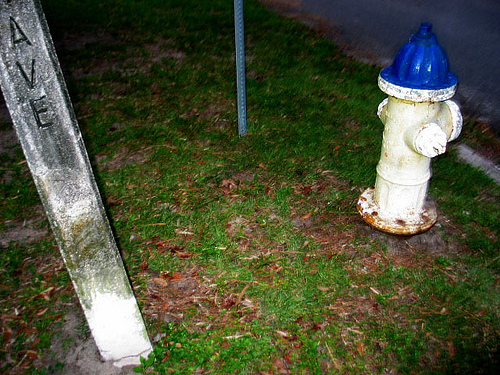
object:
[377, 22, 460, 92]
top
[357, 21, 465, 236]
fire hydrant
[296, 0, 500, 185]
road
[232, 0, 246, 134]
pole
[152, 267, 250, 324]
leaves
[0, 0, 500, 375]
ground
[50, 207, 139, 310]
moss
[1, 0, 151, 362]
post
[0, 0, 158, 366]
pillar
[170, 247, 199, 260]
leaf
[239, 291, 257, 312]
leaf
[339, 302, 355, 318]
leaf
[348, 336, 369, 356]
leaf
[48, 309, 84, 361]
patch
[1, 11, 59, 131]
ave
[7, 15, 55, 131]
letters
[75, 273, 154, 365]
smudges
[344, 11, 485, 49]
concrete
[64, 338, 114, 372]
dirt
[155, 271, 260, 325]
patches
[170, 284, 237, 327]
leaves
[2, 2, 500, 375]
grass